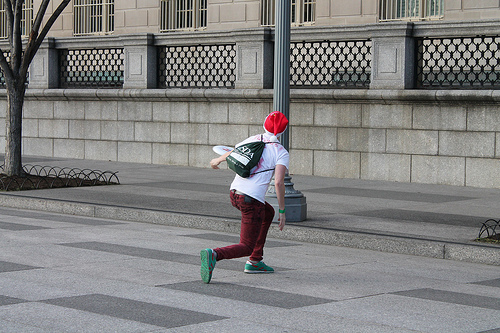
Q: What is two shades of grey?
A: The sidewalk.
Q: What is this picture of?
A: A person crossing the road.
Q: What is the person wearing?
A: A white shirt, brown trousers, red Santa cap and green shoes.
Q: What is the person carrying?
A: A backpack.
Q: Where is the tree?
A: On the sidewalk.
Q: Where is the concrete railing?
A: On the upper walkway.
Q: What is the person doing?
A: Walking.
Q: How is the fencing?
A: Black and patterned.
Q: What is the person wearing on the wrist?
A: A green wristband.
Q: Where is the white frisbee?
A: In air near the person's hand.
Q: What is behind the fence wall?
A: A building.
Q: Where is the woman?
A: Outside a building.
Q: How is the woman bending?
A: On one knee.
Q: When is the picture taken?
A: During the day.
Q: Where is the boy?
A: On the street.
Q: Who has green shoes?
A: The boy.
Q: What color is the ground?
A: Gray.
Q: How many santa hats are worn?
A: One.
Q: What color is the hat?
A: Red.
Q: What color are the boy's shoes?
A: Green.